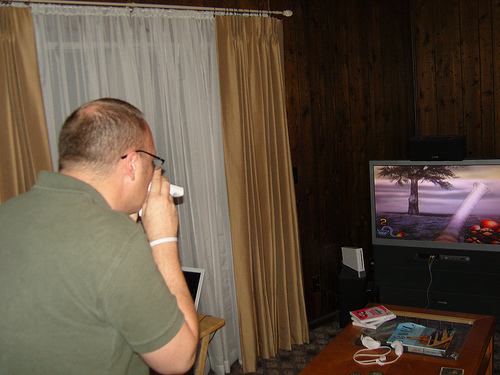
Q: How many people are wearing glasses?
A: 1.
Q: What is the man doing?
A: Playing Wii.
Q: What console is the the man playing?
A: Wii.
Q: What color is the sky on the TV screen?
A: Purple.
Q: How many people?
A: 1.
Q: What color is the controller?
A: White.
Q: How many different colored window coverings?
A: 2.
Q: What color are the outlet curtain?
A: Gold.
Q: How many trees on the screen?
A: 1.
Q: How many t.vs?
A: 1.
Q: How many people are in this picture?
A: 1.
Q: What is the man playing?
A: Wii.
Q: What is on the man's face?
A: Eyeglasses.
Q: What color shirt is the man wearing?
A: Green.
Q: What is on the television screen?
A: Wii game.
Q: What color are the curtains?
A: White and gold.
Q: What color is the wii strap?
A: White.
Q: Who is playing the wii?
A: Man with green shirt.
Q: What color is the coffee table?
A: Brown.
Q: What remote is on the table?
A: White wii remote.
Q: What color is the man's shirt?
A: Green.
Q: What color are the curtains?
A: Gold and white.